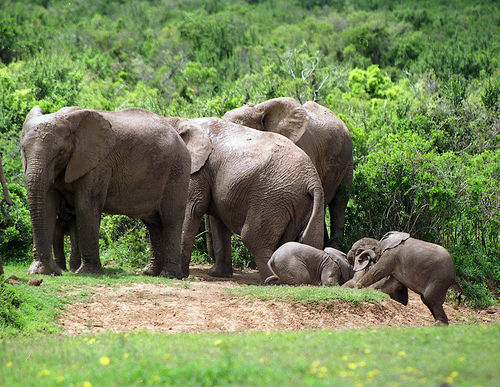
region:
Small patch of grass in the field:
[16, 352, 54, 386]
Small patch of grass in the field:
[52, 350, 92, 382]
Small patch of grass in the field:
[76, 334, 131, 359]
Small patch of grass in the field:
[92, 350, 134, 383]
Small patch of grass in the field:
[129, 328, 172, 357]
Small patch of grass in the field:
[141, 347, 197, 377]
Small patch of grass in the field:
[181, 321, 241, 357]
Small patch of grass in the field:
[192, 345, 244, 385]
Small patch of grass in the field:
[246, 335, 313, 358]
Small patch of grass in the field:
[307, 355, 394, 380]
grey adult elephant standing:
[17, 99, 204, 280]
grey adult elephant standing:
[155, 101, 332, 279]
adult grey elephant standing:
[208, 93, 363, 253]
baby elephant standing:
[346, 220, 461, 339]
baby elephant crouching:
[265, 236, 358, 284]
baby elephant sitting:
[335, 233, 410, 310]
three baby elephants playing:
[258, 225, 461, 328]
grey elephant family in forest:
[17, 76, 464, 323]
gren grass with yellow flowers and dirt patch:
[5, 283, 497, 382]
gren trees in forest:
[8, 0, 498, 306]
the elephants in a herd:
[20, 96, 465, 323]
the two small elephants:
[265, 230, 465, 326]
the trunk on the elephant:
[25, 160, 63, 275]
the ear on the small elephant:
[375, 230, 410, 258]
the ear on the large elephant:
[63, 110, 115, 182]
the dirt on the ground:
[47, 260, 498, 335]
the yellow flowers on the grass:
[0, 333, 497, 385]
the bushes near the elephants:
[0, 0, 497, 264]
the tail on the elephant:
[299, 185, 319, 245]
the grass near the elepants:
[0, 253, 499, 385]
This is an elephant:
[13, 86, 193, 297]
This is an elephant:
[155, 111, 332, 293]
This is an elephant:
[218, 91, 375, 262]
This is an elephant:
[359, 228, 471, 321]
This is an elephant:
[259, 234, 354, 320]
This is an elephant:
[343, 233, 399, 305]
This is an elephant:
[320, 231, 374, 304]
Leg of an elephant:
[70, 187, 102, 269]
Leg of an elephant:
[155, 194, 196, 309]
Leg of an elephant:
[206, 201, 252, 311]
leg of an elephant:
[53, 230, 67, 275]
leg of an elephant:
[83, 219, 108, 261]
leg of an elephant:
[70, 231, 87, 270]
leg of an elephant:
[140, 227, 163, 279]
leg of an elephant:
[163, 210, 200, 257]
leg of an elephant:
[203, 234, 226, 259]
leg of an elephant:
[336, 262, 376, 293]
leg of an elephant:
[413, 287, 455, 327]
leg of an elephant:
[323, 202, 365, 235]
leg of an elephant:
[239, 242, 287, 288]